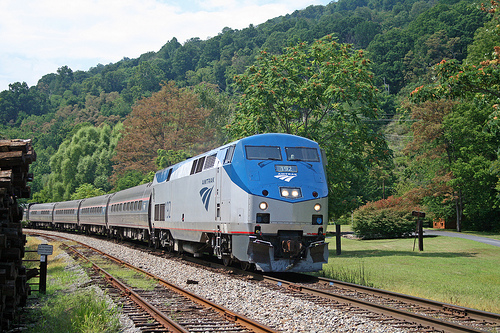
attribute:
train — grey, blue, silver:
[39, 122, 351, 290]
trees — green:
[302, 17, 438, 124]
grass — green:
[371, 249, 424, 292]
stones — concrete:
[239, 293, 280, 318]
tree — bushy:
[252, 41, 386, 129]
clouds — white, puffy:
[44, 1, 151, 43]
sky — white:
[111, 2, 166, 42]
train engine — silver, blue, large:
[219, 221, 342, 277]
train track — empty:
[132, 279, 205, 322]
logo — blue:
[196, 184, 220, 212]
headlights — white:
[273, 184, 306, 200]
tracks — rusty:
[315, 279, 360, 299]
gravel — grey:
[178, 272, 212, 290]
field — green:
[444, 234, 498, 262]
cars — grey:
[35, 193, 127, 225]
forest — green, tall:
[79, 69, 179, 105]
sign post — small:
[33, 243, 55, 264]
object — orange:
[430, 214, 448, 234]